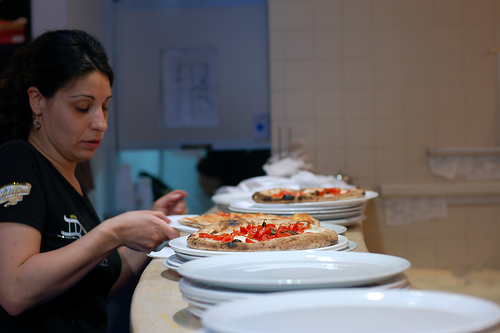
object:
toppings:
[209, 221, 321, 241]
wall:
[103, 0, 269, 213]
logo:
[0, 181, 36, 208]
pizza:
[185, 216, 338, 249]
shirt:
[0, 139, 124, 332]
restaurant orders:
[379, 181, 497, 229]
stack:
[220, 190, 375, 232]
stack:
[162, 234, 349, 265]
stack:
[176, 251, 412, 322]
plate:
[248, 184, 378, 207]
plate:
[163, 209, 348, 235]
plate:
[167, 234, 355, 257]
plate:
[177, 246, 411, 292]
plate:
[202, 287, 500, 332]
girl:
[0, 27, 187, 332]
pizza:
[178, 209, 261, 229]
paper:
[155, 42, 224, 130]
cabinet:
[112, 5, 271, 147]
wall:
[266, 0, 500, 270]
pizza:
[249, 185, 367, 205]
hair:
[3, 29, 114, 136]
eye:
[74, 102, 90, 112]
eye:
[102, 102, 118, 109]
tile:
[311, 118, 348, 153]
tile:
[341, 87, 378, 119]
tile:
[340, 55, 377, 90]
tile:
[279, 23, 314, 61]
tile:
[340, 27, 375, 58]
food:
[244, 236, 257, 242]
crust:
[190, 228, 332, 252]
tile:
[340, 119, 378, 151]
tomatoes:
[250, 225, 272, 238]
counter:
[124, 182, 419, 329]